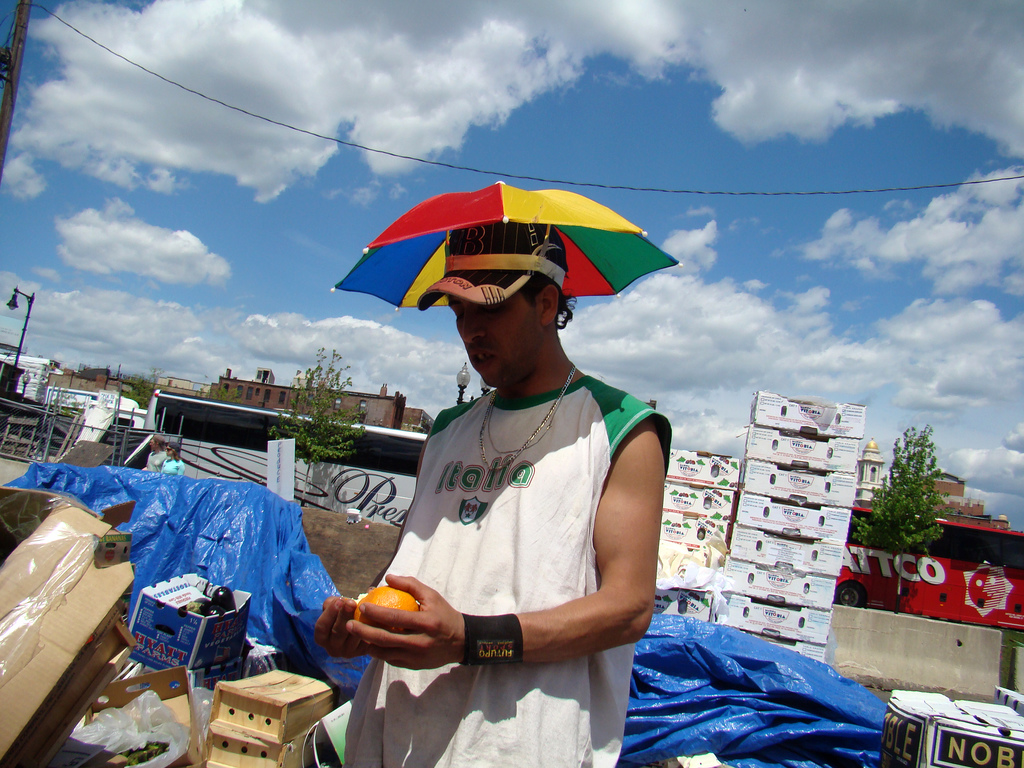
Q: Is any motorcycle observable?
A: No, there are no motorcycles.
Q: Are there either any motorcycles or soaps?
A: No, there are no motorcycles or soaps.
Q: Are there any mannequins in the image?
A: No, there are no mannequins.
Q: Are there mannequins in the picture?
A: No, there are no mannequins.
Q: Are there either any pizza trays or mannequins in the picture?
A: No, there are no mannequins or pizza trays.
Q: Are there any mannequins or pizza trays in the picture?
A: No, there are no mannequins or pizza trays.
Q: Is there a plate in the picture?
A: No, there are no plates.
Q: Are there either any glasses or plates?
A: No, there are no plates or glasses.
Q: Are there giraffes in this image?
A: No, there are no giraffes.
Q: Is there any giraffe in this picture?
A: No, there are no giraffes.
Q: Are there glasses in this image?
A: No, there are no glasses.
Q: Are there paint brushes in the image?
A: No, there are no paint brushes.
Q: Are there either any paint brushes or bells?
A: No, there are no paint brushes or bells.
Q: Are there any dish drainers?
A: No, there are no dish drainers.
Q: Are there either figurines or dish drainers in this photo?
A: No, there are no dish drainers or figurines.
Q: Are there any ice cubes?
A: No, there are no ice cubes.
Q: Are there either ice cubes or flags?
A: No, there are no ice cubes or flags.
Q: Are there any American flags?
A: No, there are no American flags.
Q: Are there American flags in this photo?
A: No, there are no American flags.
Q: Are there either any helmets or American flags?
A: No, there are no American flags or helmets.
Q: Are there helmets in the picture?
A: No, there are no helmets.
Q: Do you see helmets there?
A: No, there are no helmets.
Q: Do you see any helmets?
A: No, there are no helmets.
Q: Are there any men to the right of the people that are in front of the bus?
A: Yes, there is a man to the right of the people.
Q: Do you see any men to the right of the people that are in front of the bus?
A: Yes, there is a man to the right of the people.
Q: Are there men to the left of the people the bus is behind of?
A: No, the man is to the right of the people.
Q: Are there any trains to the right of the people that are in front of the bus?
A: No, there is a man to the right of the people.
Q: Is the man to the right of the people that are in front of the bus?
A: Yes, the man is to the right of the people.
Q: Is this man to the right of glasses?
A: No, the man is to the right of the people.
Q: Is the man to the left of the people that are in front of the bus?
A: No, the man is to the right of the people.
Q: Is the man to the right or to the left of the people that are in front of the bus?
A: The man is to the right of the people.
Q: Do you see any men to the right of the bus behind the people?
A: Yes, there is a man to the right of the bus.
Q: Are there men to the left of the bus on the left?
A: No, the man is to the right of the bus.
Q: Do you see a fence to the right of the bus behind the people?
A: No, there is a man to the right of the bus.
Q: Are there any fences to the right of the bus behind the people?
A: No, there is a man to the right of the bus.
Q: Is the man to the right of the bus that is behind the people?
A: Yes, the man is to the right of the bus.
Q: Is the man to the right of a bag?
A: No, the man is to the right of the bus.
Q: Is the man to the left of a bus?
A: No, the man is to the right of a bus.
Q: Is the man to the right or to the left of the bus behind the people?
A: The man is to the right of the bus.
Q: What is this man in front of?
A: The man is in front of the box.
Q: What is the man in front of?
A: The man is in front of the box.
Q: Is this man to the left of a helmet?
A: No, the man is to the left of the bus.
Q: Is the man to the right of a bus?
A: No, the man is to the left of a bus.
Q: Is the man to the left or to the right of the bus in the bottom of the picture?
A: The man is to the left of the bus.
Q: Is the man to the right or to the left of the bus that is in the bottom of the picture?
A: The man is to the left of the bus.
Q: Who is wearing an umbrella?
A: The man is wearing an umbrella.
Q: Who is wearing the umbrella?
A: The man is wearing an umbrella.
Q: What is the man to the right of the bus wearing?
A: The man is wearing an umbrella.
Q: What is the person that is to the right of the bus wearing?
A: The man is wearing an umbrella.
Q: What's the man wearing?
A: The man is wearing an umbrella.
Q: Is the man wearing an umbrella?
A: Yes, the man is wearing an umbrella.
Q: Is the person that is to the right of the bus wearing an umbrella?
A: Yes, the man is wearing an umbrella.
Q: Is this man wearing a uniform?
A: No, the man is wearing an umbrella.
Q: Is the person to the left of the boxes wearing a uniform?
A: No, the man is wearing an umbrella.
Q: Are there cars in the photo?
A: No, there are no cars.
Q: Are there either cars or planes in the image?
A: No, there are no cars or planes.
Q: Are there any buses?
A: Yes, there is a bus.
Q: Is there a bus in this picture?
A: Yes, there is a bus.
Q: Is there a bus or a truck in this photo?
A: Yes, there is a bus.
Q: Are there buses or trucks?
A: Yes, there is a bus.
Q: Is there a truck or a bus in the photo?
A: Yes, there is a bus.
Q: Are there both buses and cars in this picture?
A: No, there is a bus but no cars.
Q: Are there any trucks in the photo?
A: No, there are no trucks.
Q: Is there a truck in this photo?
A: No, there are no trucks.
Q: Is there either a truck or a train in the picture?
A: No, there are no trucks or trains.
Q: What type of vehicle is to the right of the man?
A: The vehicle is a bus.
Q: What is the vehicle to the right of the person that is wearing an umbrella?
A: The vehicle is a bus.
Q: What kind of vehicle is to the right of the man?
A: The vehicle is a bus.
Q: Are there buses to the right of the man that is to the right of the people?
A: Yes, there is a bus to the right of the man.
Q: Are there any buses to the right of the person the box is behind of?
A: Yes, there is a bus to the right of the man.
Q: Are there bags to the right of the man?
A: No, there is a bus to the right of the man.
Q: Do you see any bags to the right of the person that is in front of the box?
A: No, there is a bus to the right of the man.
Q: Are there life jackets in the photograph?
A: No, there are no life jackets.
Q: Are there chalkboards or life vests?
A: No, there are no life vests or chalkboards.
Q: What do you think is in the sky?
A: The clouds are in the sky.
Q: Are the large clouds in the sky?
A: Yes, the clouds are in the sky.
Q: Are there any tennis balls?
A: No, there are no tennis balls.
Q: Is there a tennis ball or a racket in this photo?
A: No, there are no tennis balls or rackets.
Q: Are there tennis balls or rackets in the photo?
A: No, there are no tennis balls or rackets.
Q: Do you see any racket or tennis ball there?
A: No, there are no tennis balls or rackets.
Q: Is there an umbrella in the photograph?
A: Yes, there is an umbrella.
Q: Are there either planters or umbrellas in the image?
A: Yes, there is an umbrella.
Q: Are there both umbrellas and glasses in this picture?
A: No, there is an umbrella but no glasses.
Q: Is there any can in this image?
A: No, there are no cans.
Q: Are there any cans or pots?
A: No, there are no cans or pots.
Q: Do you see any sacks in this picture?
A: No, there are no sacks.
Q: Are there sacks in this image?
A: No, there are no sacks.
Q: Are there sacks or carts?
A: No, there are no sacks or carts.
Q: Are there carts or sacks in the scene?
A: No, there are no sacks or carts.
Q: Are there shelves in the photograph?
A: No, there are no shelves.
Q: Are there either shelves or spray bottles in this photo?
A: No, there are no shelves or spray bottles.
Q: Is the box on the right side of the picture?
A: Yes, the box is on the right of the image.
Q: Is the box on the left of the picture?
A: No, the box is on the right of the image.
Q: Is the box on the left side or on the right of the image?
A: The box is on the right of the image.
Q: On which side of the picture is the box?
A: The box is on the right of the image.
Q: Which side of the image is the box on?
A: The box is on the right of the image.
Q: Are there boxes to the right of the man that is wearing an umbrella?
A: Yes, there is a box to the right of the man.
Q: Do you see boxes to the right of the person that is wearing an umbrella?
A: Yes, there is a box to the right of the man.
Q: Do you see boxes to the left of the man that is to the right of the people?
A: No, the box is to the right of the man.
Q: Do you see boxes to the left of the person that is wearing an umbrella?
A: No, the box is to the right of the man.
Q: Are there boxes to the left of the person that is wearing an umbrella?
A: No, the box is to the right of the man.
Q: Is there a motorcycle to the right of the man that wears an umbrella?
A: No, there is a box to the right of the man.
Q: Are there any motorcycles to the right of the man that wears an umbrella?
A: No, there is a box to the right of the man.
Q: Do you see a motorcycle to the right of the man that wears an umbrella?
A: No, there is a box to the right of the man.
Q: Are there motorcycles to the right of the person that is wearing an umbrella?
A: No, there is a box to the right of the man.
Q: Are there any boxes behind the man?
A: Yes, there is a box behind the man.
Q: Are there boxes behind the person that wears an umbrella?
A: Yes, there is a box behind the man.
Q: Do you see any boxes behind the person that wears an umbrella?
A: Yes, there is a box behind the man.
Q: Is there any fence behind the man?
A: No, there is a box behind the man.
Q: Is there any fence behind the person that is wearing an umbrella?
A: No, there is a box behind the man.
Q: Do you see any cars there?
A: No, there are no cars.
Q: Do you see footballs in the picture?
A: No, there are no footballs.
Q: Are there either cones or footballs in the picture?
A: No, there are no footballs or cones.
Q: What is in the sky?
A: The clouds are in the sky.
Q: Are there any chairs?
A: No, there are no chairs.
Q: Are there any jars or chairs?
A: No, there are no chairs or jars.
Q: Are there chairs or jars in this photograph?
A: No, there are no chairs or jars.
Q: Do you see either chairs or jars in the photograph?
A: No, there are no chairs or jars.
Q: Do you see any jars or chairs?
A: No, there are no chairs or jars.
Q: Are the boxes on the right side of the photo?
A: Yes, the boxes are on the right of the image.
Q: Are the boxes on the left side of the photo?
A: No, the boxes are on the right of the image.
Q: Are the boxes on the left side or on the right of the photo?
A: The boxes are on the right of the image.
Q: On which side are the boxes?
A: The boxes are on the right of the image.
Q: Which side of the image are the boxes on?
A: The boxes are on the right of the image.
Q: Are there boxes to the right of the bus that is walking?
A: Yes, there are boxes to the right of the bus.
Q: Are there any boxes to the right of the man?
A: Yes, there are boxes to the right of the man.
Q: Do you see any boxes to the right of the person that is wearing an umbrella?
A: Yes, there are boxes to the right of the man.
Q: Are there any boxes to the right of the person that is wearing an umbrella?
A: Yes, there are boxes to the right of the man.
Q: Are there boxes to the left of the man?
A: No, the boxes are to the right of the man.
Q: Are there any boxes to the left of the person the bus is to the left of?
A: No, the boxes are to the right of the man.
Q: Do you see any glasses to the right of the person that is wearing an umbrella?
A: No, there are boxes to the right of the man.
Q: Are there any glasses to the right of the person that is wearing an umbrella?
A: No, there are boxes to the right of the man.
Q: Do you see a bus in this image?
A: Yes, there is a bus.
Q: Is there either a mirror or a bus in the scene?
A: Yes, there is a bus.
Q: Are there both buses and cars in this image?
A: No, there is a bus but no cars.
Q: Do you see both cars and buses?
A: No, there is a bus but no cars.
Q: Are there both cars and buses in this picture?
A: No, there is a bus but no cars.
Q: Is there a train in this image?
A: No, there are no trains.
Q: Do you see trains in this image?
A: No, there are no trains.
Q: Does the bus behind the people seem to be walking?
A: Yes, the bus is walking.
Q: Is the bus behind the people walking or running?
A: The bus is walking.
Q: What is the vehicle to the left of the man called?
A: The vehicle is a bus.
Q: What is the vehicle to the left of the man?
A: The vehicle is a bus.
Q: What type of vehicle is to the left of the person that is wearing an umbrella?
A: The vehicle is a bus.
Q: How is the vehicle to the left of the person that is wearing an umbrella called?
A: The vehicle is a bus.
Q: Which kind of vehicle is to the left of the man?
A: The vehicle is a bus.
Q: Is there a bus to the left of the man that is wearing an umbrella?
A: Yes, there is a bus to the left of the man.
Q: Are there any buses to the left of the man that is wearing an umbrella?
A: Yes, there is a bus to the left of the man.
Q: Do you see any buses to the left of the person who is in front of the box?
A: Yes, there is a bus to the left of the man.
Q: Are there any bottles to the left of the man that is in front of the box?
A: No, there is a bus to the left of the man.